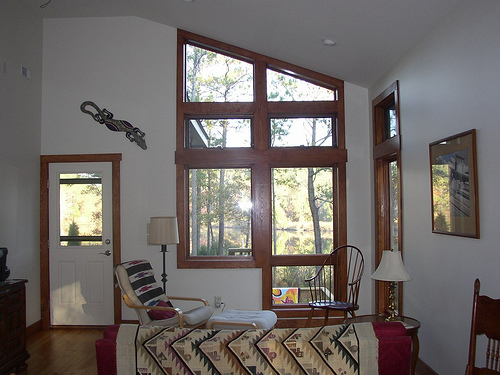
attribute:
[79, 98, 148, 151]
gecko figurine — metal, black, artistic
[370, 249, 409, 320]
lamp — bronze, short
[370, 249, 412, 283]
lamp shade — white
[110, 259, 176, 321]
blanket — native american, woven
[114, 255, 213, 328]
chair — white, tan, wooden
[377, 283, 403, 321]
base — brass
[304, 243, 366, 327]
chair — wooden, brown, windsor style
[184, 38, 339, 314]
window — large, multipaned, odd shaped, trapezoid shaped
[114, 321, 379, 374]
blanket — tan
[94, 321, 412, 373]
couch — red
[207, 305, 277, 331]
ottoman — cushioned, tan, padded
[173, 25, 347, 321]
frame — wooden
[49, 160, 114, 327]
door — white, wooden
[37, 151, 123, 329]
door frame — wooden, dark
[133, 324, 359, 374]
design — native american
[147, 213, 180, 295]
floor lamp — black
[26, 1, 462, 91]
ceiling — white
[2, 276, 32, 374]
chest — wooden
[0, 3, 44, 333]
wall — white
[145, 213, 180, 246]
lamp shade — white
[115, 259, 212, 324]
cushion — white